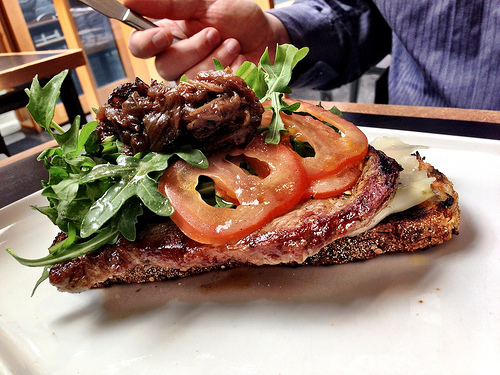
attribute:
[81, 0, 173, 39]
knife — metal, silver, colored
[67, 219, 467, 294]
meat — some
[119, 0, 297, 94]
hand — man's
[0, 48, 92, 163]
table — wooden framed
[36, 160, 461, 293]
meat — grilled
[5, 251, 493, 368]
plate — clean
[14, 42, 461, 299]
food — stacked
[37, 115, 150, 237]
lettuce — green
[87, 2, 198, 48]
knife — silver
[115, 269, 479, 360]
plate — white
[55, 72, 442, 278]
sandwich — some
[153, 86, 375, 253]
tomatoe slices — tomato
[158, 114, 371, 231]
slices — of tomato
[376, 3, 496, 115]
stripes — blue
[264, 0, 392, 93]
sleeve — man's